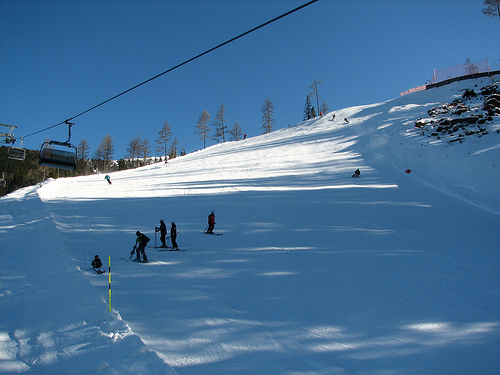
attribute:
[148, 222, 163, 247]
pole — ski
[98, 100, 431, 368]
slope — ski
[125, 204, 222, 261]
people — skiing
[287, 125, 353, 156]
shadow — dark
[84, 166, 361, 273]
skiiers — group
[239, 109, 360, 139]
skiiers — group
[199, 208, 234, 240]
skier — wearing black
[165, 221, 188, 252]
skier — wearing black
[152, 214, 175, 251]
skier — wearing black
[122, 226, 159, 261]
skier — wearing black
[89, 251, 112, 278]
skier — wearing black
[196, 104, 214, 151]
pine tree — these, some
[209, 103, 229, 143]
pine tree — these, some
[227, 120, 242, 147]
pine tree — these, some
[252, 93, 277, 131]
pine tree — these, some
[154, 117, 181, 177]
pine tree — these, some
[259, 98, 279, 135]
tree — old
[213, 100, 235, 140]
tree — old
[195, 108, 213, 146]
tree — old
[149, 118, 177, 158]
tree — old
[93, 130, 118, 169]
tree — old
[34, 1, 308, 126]
cable — black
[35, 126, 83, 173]
ski lift — moving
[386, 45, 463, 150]
trees — bare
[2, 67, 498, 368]
snow — white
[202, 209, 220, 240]
people — skiing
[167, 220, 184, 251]
people — skiing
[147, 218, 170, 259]
people — skiing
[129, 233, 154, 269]
people — skiing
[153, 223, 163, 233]
hand — someone's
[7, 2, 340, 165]
lift — ski